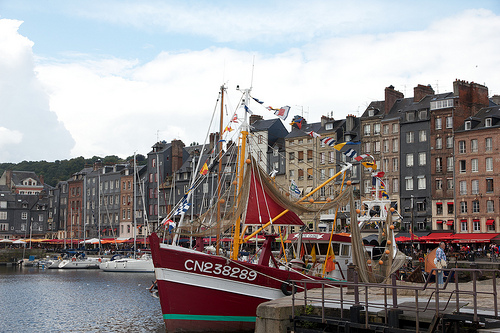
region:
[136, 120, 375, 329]
A large red boat in the harbor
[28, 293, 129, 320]
The water looks very calm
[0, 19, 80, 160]
A large fluffy white cloud in the sky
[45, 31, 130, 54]
A patch of clear blue sky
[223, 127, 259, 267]
A yellow mast on the ship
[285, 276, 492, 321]
A wooden dock by the ship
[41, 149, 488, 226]
A row of building behind the boats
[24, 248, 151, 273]
Numerous small boats in the water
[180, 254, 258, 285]
White writing on the red ship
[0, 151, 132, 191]
A tree line in the distance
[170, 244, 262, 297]
white letter and numbers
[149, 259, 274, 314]
white stripe on side of boat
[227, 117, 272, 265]
orange painted pole on boat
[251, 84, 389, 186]
lots of different flags on a rope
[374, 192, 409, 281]
rope with orange balls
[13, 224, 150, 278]
boat parked near building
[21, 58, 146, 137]
big clouds in the sky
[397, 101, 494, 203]
narrow building connected to eachother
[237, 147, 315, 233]
red sail on a boat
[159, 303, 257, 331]
green stripe on side of red boat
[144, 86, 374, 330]
a large red sailboat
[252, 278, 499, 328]
a concrete boat dock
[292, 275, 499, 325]
brown metal fencing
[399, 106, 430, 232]
a tall black building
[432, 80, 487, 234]
a tall red brick building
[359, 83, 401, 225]
a ball brick building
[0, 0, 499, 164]
a cloudy blue sky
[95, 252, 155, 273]
a docked white boat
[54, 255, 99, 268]
a docked white boat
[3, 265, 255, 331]
a body of water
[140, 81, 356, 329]
red and white boat in body of water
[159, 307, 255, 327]
green stripe on bottom of red and white boat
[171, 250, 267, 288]
white numbers and letters on side of boat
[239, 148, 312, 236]
red sail on top of boat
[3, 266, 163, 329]
body of water in front of buildings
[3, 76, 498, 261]
tall buildings in front of water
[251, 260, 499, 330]
pier on the side of a boat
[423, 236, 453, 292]
person in blue outfit standing on pier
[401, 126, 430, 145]
two windows on front of grey building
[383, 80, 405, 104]
chimney on topf of building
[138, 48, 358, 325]
a red boat by the dock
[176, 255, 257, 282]
an identification number painted on the boat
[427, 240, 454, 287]
a man in blue standing on the dock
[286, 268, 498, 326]
a metal raining on the edge of the dock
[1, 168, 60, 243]
a grey house at the end of the row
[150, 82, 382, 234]
colorful pennants in the rigging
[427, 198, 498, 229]
red awnings over the windows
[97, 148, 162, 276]
a white boat at another dock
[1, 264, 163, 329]
the water of the bay